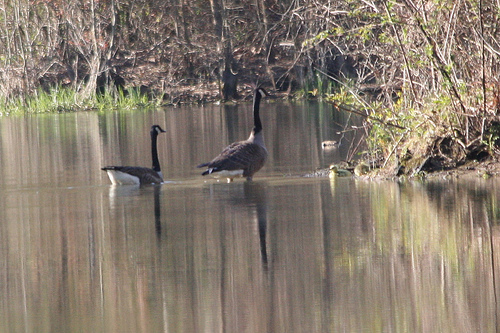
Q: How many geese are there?
A: Two.